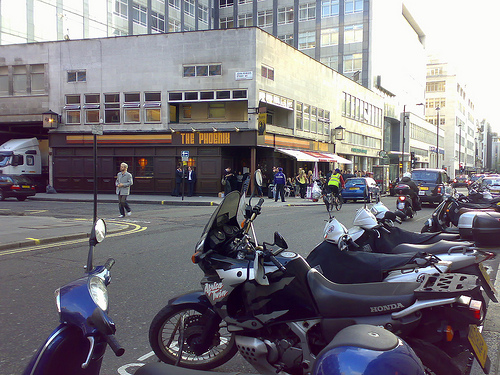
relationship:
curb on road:
[87, 212, 144, 239] [2, 195, 438, 370]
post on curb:
[93, 133, 98, 233] [87, 212, 144, 239]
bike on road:
[148, 190, 490, 375] [2, 195, 438, 370]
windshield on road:
[197, 188, 240, 254] [2, 195, 438, 370]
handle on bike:
[101, 332, 129, 357] [19, 221, 429, 374]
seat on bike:
[307, 266, 418, 316] [149, 178, 498, 372]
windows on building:
[65, 94, 162, 126] [0, 26, 383, 194]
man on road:
[115, 162, 133, 217] [2, 195, 438, 370]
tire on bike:
[148, 298, 238, 370] [149, 178, 498, 372]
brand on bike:
[370, 300, 406, 316] [149, 178, 498, 372]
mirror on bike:
[253, 167, 267, 189] [149, 178, 498, 372]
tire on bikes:
[148, 298, 238, 370] [30, 191, 496, 374]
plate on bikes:
[466, 322, 493, 372] [30, 191, 496, 374]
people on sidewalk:
[216, 165, 316, 200] [36, 183, 326, 210]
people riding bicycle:
[328, 168, 345, 206] [323, 188, 342, 212]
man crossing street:
[115, 162, 133, 217] [0, 197, 436, 374]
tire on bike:
[149, 298, 238, 370] [148, 190, 490, 375]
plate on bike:
[466, 322, 493, 372] [149, 178, 498, 372]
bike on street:
[148, 190, 490, 375] [0, 197, 436, 374]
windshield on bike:
[197, 188, 240, 254] [148, 190, 490, 375]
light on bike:
[445, 327, 455, 342] [148, 190, 490, 375]